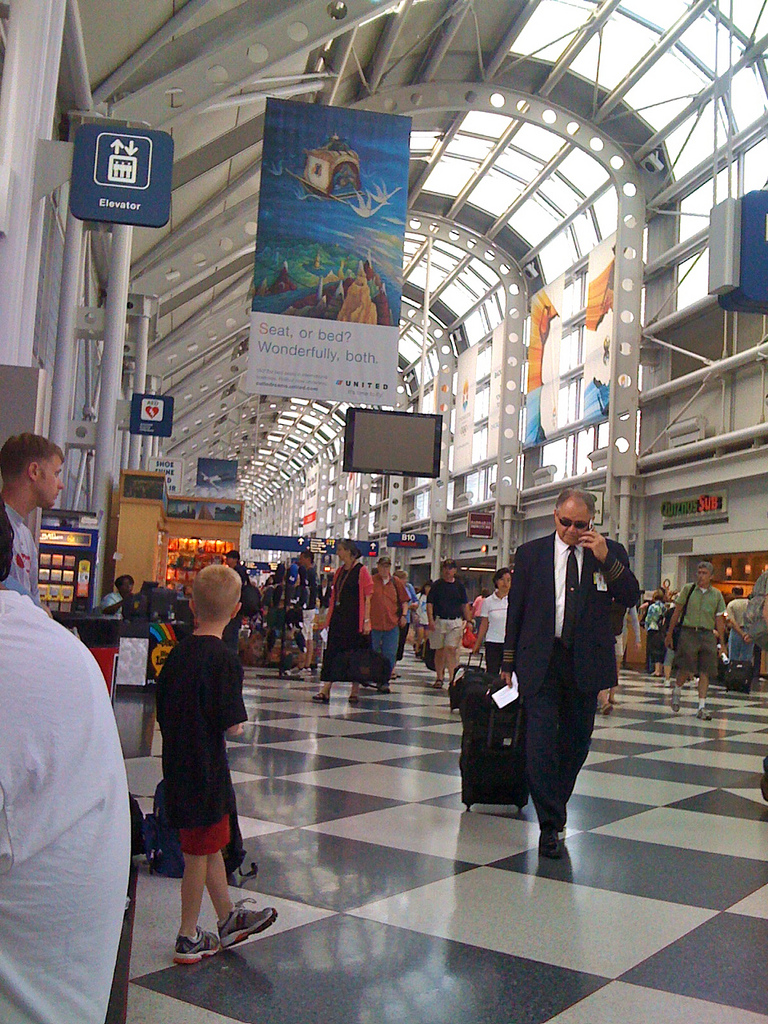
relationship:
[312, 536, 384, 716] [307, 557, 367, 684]
woman wearing dress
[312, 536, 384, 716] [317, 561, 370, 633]
woman wearing coat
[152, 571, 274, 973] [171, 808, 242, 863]
boy wearing shorts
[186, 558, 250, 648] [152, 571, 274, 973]
head on boy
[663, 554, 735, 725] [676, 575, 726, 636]
man wearing shirt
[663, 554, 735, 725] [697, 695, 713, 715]
man wearing socks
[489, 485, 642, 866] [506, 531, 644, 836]
man wearing suit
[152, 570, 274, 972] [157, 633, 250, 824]
boy wearing shirt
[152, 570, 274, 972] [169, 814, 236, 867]
boy wearing shorts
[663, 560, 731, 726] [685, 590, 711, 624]
man holding white object wearing green shirt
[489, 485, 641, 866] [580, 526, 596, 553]
man talking on cellphone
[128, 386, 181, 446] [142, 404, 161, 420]
sign with heart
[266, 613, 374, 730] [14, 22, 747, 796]
wall on side of building